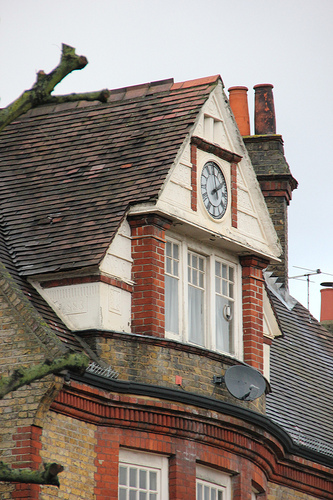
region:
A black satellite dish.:
[210, 363, 269, 405]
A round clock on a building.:
[193, 157, 233, 224]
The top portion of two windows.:
[109, 442, 243, 499]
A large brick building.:
[0, 41, 332, 499]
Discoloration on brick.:
[179, 418, 205, 467]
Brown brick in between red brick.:
[9, 421, 118, 499]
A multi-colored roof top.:
[0, 74, 220, 279]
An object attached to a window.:
[220, 301, 234, 322]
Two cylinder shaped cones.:
[229, 80, 280, 139]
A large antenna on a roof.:
[287, 260, 331, 325]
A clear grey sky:
[144, 9, 239, 61]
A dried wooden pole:
[6, 33, 119, 129]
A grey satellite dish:
[210, 362, 273, 403]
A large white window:
[120, 450, 172, 498]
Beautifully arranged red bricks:
[175, 435, 262, 454]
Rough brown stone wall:
[59, 432, 89, 454]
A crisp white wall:
[66, 287, 132, 326]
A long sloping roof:
[43, 115, 111, 235]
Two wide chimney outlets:
[230, 83, 279, 127]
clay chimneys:
[230, 83, 276, 136]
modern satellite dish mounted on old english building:
[215, 360, 268, 404]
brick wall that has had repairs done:
[6, 372, 330, 497]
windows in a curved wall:
[114, 447, 266, 498]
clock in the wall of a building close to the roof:
[188, 135, 242, 226]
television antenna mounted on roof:
[286, 263, 331, 312]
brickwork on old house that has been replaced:
[129, 222, 268, 373]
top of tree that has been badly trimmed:
[0, 41, 111, 131]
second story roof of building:
[1, 73, 223, 280]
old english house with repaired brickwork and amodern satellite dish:
[8, 75, 331, 498]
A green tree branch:
[0, 42, 110, 131]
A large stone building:
[0, 73, 332, 497]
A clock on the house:
[200, 157, 229, 222]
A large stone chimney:
[227, 82, 298, 292]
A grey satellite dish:
[212, 363, 266, 402]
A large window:
[165, 233, 240, 355]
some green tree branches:
[0, 352, 88, 486]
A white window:
[118, 447, 168, 499]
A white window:
[196, 464, 230, 499]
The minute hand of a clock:
[212, 162, 219, 200]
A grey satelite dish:
[213, 363, 267, 401]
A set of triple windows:
[162, 227, 246, 364]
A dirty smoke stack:
[252, 83, 277, 135]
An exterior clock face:
[199, 159, 230, 222]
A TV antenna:
[286, 264, 331, 324]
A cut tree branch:
[0, 42, 109, 128]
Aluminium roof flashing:
[261, 267, 298, 310]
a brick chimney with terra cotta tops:
[226, 85, 297, 300]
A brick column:
[124, 210, 175, 338]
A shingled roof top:
[0, 71, 221, 376]